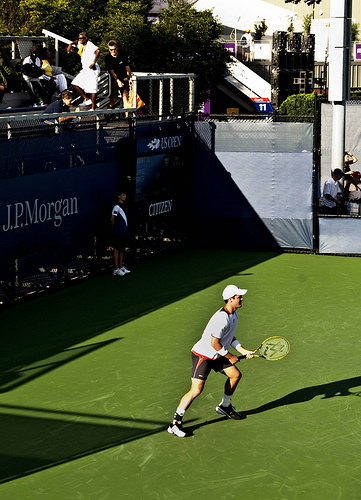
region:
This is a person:
[158, 275, 303, 449]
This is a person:
[98, 180, 160, 287]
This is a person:
[317, 159, 350, 216]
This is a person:
[98, 34, 145, 121]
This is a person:
[64, 21, 103, 115]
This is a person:
[21, 30, 62, 113]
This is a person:
[64, 20, 108, 116]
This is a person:
[101, 33, 139, 120]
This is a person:
[100, 179, 147, 283]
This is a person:
[319, 152, 360, 219]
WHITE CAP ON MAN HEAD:
[226, 285, 239, 294]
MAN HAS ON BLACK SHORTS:
[201, 366, 206, 372]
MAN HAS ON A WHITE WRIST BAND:
[216, 347, 227, 357]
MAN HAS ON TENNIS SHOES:
[171, 420, 185, 436]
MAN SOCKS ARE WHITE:
[178, 406, 182, 412]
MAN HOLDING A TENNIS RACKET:
[226, 336, 292, 357]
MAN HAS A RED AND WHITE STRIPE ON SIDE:
[193, 355, 204, 372]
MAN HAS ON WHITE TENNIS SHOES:
[113, 267, 130, 275]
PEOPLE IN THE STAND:
[27, 26, 127, 131]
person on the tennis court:
[157, 277, 318, 461]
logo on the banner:
[148, 195, 184, 222]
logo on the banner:
[135, 125, 191, 160]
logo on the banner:
[0, 196, 86, 235]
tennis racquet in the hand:
[241, 322, 302, 384]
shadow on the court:
[265, 365, 348, 418]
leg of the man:
[168, 400, 196, 444]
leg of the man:
[212, 378, 257, 427]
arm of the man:
[207, 346, 238, 364]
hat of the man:
[218, 286, 251, 297]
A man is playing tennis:
[161, 280, 294, 442]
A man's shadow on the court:
[180, 372, 358, 439]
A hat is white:
[217, 280, 250, 302]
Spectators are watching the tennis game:
[1, 28, 130, 115]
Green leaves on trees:
[1, 1, 236, 109]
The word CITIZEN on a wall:
[145, 195, 179, 219]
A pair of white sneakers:
[105, 263, 132, 280]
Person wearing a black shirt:
[98, 39, 135, 83]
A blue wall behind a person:
[3, 116, 197, 302]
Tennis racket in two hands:
[225, 333, 295, 369]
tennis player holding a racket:
[160, 267, 298, 443]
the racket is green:
[242, 329, 292, 364]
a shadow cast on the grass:
[245, 369, 360, 437]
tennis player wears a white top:
[163, 280, 258, 440]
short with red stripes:
[184, 348, 229, 384]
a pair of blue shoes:
[162, 400, 249, 438]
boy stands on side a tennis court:
[108, 185, 138, 279]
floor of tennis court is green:
[65, 241, 351, 498]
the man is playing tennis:
[173, 287, 276, 434]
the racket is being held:
[239, 335, 286, 360]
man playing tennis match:
[164, 280, 266, 439]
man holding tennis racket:
[227, 332, 294, 370]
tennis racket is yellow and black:
[229, 330, 290, 371]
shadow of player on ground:
[183, 366, 359, 441]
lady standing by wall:
[107, 186, 135, 279]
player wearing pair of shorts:
[182, 344, 234, 382]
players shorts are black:
[185, 342, 236, 381]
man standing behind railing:
[102, 37, 134, 112]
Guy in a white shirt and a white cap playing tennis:
[167, 284, 290, 437]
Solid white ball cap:
[220, 284, 248, 300]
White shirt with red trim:
[190, 309, 242, 356]